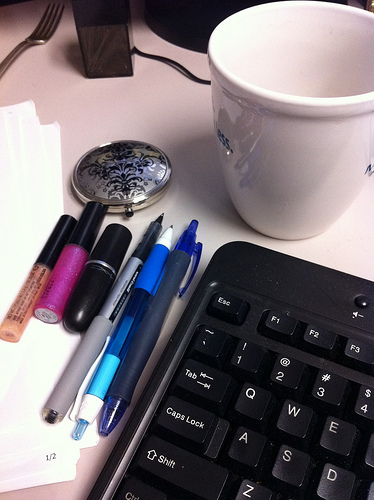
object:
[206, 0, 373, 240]
cup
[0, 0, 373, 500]
desktop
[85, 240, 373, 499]
keyboard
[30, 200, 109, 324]
container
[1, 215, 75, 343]
container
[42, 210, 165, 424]
pen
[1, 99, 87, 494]
papers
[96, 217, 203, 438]
items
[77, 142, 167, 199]
design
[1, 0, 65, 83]
fork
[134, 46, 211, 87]
cord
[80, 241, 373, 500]
corner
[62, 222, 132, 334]
lip gloss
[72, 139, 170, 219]
pocket watch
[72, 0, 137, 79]
box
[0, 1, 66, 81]
corner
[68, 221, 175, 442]
pens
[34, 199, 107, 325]
lip gloss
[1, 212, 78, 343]
lip gloss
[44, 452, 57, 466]
numbers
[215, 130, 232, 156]
blue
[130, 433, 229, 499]
shift key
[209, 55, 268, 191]
reflection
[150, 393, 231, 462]
caps lock button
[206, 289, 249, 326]
esc button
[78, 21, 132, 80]
paper clips